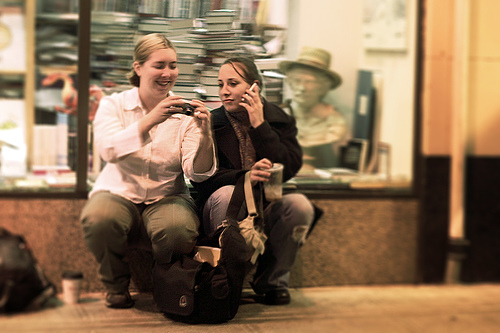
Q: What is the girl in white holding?
A: Camera.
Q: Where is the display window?
A: Behind the women.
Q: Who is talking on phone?
A: Woman in black jacket.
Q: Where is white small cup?
A: Beside woman in white shirt.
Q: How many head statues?
A: One.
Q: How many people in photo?
A: Two.